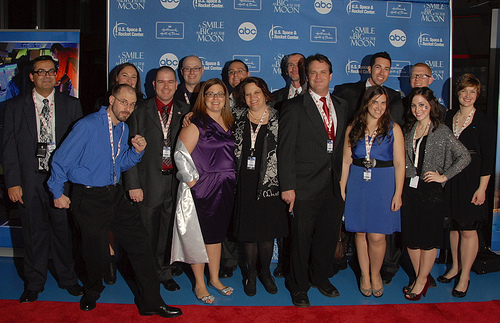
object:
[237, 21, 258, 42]
logo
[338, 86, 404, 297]
woman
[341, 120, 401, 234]
dress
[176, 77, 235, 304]
woman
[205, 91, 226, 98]
glasses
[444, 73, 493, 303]
woman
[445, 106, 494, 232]
dress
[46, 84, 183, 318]
man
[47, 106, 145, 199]
shirt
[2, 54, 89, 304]
man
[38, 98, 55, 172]
tie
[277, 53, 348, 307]
man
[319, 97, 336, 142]
tie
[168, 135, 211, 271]
wrap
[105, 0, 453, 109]
background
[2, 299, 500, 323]
carpet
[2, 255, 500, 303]
floor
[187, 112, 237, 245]
dress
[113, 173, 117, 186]
tag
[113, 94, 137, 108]
glasses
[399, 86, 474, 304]
woman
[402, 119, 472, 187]
sweater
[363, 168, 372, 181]
tag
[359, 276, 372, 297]
sandle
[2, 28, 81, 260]
sign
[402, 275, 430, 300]
heels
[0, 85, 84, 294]
suit